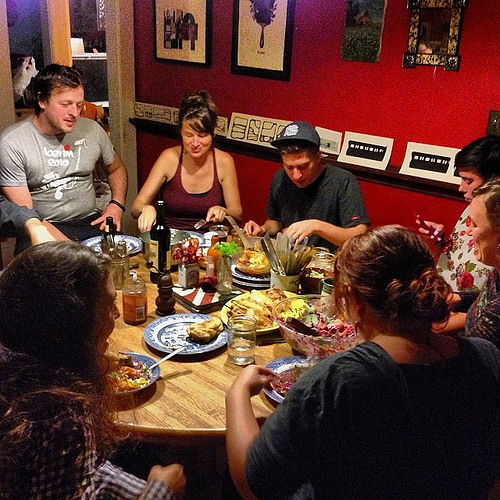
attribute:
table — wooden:
[94, 208, 362, 432]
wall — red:
[328, 71, 471, 128]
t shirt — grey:
[1, 107, 123, 244]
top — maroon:
[157, 140, 229, 235]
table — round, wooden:
[50, 225, 434, 467]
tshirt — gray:
[1, 112, 117, 223]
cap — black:
[268, 121, 321, 149]